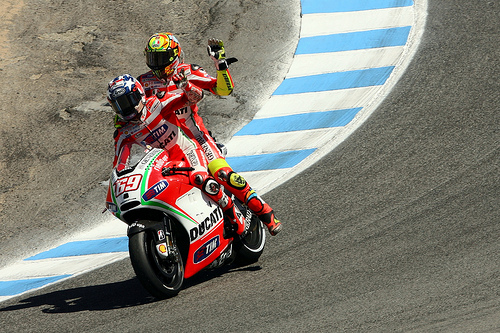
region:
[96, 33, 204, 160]
racers are wearing helmets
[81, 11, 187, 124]
racers are wearing helmets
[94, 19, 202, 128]
racers are wearing helmets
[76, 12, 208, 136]
racers are wearing helmets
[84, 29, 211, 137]
racers are wearing helmets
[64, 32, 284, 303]
two people riding a motorcycle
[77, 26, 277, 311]
two people riding a motorcycle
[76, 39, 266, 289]
two people riding a motorcycle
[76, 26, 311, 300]
two men riding a motorcycle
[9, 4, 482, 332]
men in a motorcycle race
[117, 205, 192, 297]
front wheel of a motorcycle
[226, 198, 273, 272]
back wheel of a motorcycle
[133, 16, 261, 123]
motorcyclist holding a hand up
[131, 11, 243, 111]
motorcyclist wearing a red and yellow helmet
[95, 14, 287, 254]
men wearing red and white suits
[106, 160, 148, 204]
motorcycle number 69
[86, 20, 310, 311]
motorcycle is leaning to the left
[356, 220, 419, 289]
the road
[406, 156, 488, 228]
the road is black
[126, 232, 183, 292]
the tire is black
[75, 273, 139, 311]
a shadow on the road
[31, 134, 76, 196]
brown dirt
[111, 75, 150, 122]
the driver wearing a helmet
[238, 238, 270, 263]
the back tire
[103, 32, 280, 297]
the two people on the motorcycle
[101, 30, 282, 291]
the motorcycle under the two people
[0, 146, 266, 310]
the shadow near the motorcycle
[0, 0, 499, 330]
the blue and white on the road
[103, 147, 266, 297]
the 69 on the motorcycle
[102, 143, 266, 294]
the word DUCATI on the motorcycle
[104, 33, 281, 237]
the helmets on the people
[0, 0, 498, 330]
the road under the motorcycle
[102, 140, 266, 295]
the front wheel on the motorcycle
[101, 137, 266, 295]
the back wheel on the motorcycle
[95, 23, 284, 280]
two riders on a motorbike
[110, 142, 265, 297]
red and white motorcycle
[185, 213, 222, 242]
black lettering on the motorbike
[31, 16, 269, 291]
two people on a bike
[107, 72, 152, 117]
a helmet with a star on it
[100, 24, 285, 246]
two people riding a motorcycle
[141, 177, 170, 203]
a blue sign with red and white on it.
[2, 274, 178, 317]
a shadow of the men and motorcycle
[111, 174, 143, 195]
the number 69 trimmed in red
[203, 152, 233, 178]
a yellow band on the uniform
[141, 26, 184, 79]
a very colorful helmet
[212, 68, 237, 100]
a yellow sleeve with black writing on it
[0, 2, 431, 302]
blue and white lines in a curve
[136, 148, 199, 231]
a green line on the motorcycle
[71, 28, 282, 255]
people riding a bike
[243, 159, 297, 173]
blue lines on the dirt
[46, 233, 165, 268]
blue lines on the dirt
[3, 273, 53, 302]
blue lines on the dirt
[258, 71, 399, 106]
blue lines on the dirt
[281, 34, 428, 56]
blue lines on the dirt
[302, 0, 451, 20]
blue lines on the dirt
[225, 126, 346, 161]
white lines on the dirt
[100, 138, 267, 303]
orange and white motorcycle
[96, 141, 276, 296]
white and orange ducati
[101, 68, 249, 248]
cycle driver in orange and white suit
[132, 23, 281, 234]
cycle passenger in orange white and yellow suit